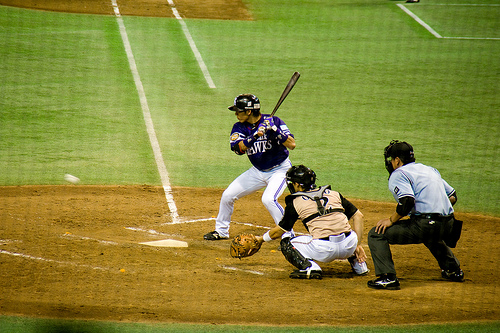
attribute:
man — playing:
[202, 91, 293, 240]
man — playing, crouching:
[367, 138, 466, 285]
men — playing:
[215, 95, 462, 287]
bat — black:
[264, 70, 300, 136]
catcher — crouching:
[263, 166, 365, 273]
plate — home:
[145, 236, 190, 250]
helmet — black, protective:
[225, 95, 264, 112]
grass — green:
[1, 8, 499, 205]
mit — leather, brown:
[227, 235, 262, 259]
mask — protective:
[284, 176, 297, 195]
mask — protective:
[385, 147, 394, 173]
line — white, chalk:
[107, 2, 185, 226]